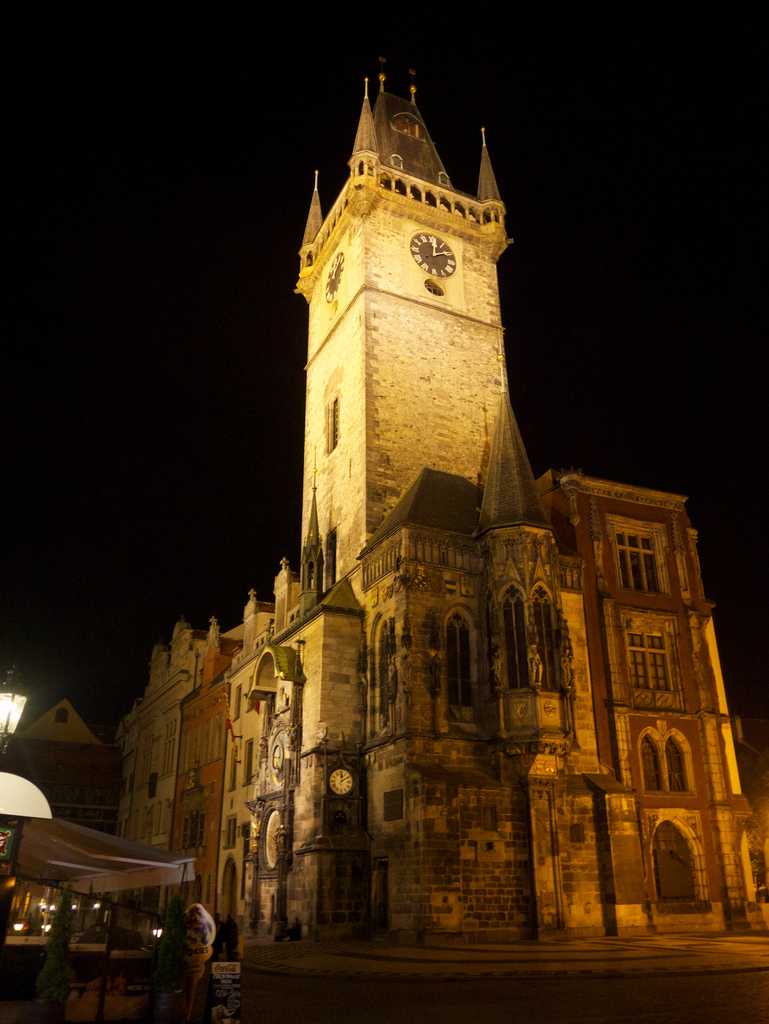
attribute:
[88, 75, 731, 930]
building — tan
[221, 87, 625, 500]
tower — tan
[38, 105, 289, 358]
sky — black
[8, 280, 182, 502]
sky — black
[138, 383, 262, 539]
sky — black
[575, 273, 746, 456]
sky — black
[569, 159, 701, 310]
sky — black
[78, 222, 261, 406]
sky — black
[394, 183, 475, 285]
clock — black, large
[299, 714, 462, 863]
clock — white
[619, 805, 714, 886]
door — brown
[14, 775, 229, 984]
tent — white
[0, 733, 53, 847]
light — white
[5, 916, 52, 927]
light — yellow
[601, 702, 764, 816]
window — arched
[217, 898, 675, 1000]
sidewalk — paved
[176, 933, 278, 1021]
sign — upright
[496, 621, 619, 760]
statue — small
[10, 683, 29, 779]
light bar — rectangular